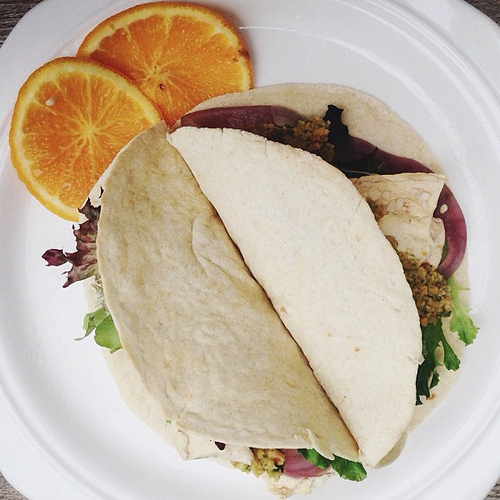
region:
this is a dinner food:
[108, 73, 493, 394]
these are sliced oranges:
[27, 64, 208, 189]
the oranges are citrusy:
[24, 64, 244, 215]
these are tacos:
[120, 135, 420, 370]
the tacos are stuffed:
[244, 95, 446, 329]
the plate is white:
[70, 403, 112, 445]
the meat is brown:
[417, 269, 443, 320]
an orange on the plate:
[30, 100, 116, 160]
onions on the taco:
[290, 458, 315, 479]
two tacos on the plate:
[101, 164, 437, 436]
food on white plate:
[0, 1, 497, 498]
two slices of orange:
[9, 1, 252, 222]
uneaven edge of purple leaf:
[42, 194, 100, 289]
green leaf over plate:
[417, 278, 477, 400]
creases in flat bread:
[185, 213, 249, 287]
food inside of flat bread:
[392, 236, 449, 325]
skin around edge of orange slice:
[74, 2, 254, 108]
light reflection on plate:
[243, 0, 497, 222]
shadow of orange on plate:
[217, 4, 259, 69]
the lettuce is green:
[417, 312, 477, 410]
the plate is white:
[7, 224, 119, 495]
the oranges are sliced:
[11, 10, 254, 222]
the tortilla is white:
[120, 249, 312, 418]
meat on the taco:
[405, 255, 453, 351]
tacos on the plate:
[96, 101, 447, 461]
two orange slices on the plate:
[7, 22, 235, 167]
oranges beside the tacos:
[15, 70, 473, 455]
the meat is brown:
[402, 252, 454, 323]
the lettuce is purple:
[67, 220, 102, 302]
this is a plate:
[6, 2, 497, 496]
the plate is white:
[9, 19, 499, 486]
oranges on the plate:
[8, 3, 288, 212]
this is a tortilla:
[150, 79, 485, 430]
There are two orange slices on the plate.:
[11, 0, 254, 202]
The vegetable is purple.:
[181, 105, 469, 277]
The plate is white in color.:
[0, 3, 495, 499]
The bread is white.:
[106, 120, 421, 470]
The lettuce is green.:
[75, 308, 121, 351]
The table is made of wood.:
[0, 2, 34, 42]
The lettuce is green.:
[420, 314, 457, 379]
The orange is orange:
[10, 62, 174, 267]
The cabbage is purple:
[30, 186, 139, 301]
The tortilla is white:
[76, 135, 363, 492]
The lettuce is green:
[59, 300, 140, 353]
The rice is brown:
[391, 241, 463, 331]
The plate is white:
[2, 45, 499, 462]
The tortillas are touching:
[82, 122, 417, 495]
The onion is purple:
[330, 131, 480, 281]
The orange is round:
[7, 55, 163, 246]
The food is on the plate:
[4, 25, 473, 496]